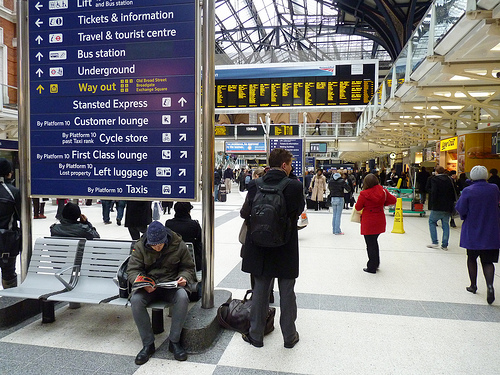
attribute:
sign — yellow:
[435, 132, 462, 152]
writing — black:
[440, 140, 454, 147]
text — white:
[74, 64, 140, 81]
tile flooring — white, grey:
[1, 191, 498, 373]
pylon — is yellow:
[391, 199, 406, 234]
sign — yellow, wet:
[391, 199, 405, 233]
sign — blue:
[28, 176, 195, 199]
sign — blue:
[28, 159, 196, 181]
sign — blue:
[30, 146, 196, 167]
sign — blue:
[30, 129, 196, 149]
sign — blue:
[27, 112, 196, 130]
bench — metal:
[0, 237, 197, 333]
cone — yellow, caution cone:
[370, 173, 428, 247]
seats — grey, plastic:
[0, 237, 191, 315]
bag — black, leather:
[217, 297, 275, 334]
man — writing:
[122, 222, 217, 362]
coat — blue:
[456, 182, 498, 250]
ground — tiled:
[14, 330, 124, 374]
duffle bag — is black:
[214, 280, 279, 335]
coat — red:
[357, 183, 397, 237]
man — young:
[239, 146, 302, 346]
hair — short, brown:
[266, 148, 291, 165]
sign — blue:
[25, 2, 200, 200]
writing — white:
[111, 100, 151, 161]